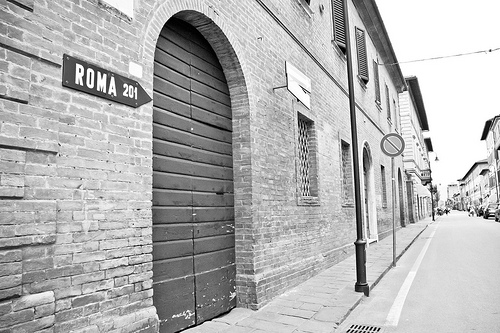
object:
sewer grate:
[344, 324, 383, 331]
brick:
[18, 102, 60, 126]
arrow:
[60, 52, 157, 108]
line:
[385, 214, 444, 330]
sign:
[380, 133, 406, 157]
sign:
[284, 60, 313, 95]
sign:
[60, 53, 152, 110]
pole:
[388, 158, 398, 269]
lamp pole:
[340, 3, 376, 294]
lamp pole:
[428, 181, 436, 222]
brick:
[100, 237, 145, 254]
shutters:
[356, 27, 369, 82]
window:
[356, 26, 370, 89]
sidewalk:
[179, 214, 437, 331]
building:
[447, 112, 498, 222]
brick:
[111, 111, 151, 132]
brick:
[124, 171, 150, 193]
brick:
[266, 182, 295, 195]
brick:
[263, 113, 281, 130]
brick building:
[0, 2, 441, 333]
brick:
[80, 177, 117, 206]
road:
[337, 210, 500, 333]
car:
[482, 201, 496, 219]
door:
[149, 19, 237, 331]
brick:
[32, 232, 75, 256]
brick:
[20, 136, 77, 166]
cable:
[382, 48, 496, 67]